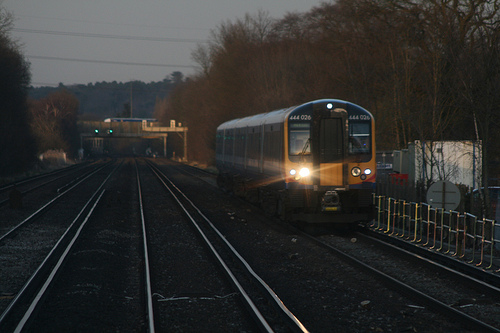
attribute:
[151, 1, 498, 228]
trees — side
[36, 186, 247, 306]
track — part, metal train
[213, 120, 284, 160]
windows — passenger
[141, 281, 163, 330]
train track — part , metal train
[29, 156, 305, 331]
track — part , metal train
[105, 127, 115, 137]
light — stop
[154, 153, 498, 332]
track — right train, train 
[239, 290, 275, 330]
train track — metal train, part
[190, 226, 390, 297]
tracks — several train , running  , parallel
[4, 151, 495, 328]
track — metal train, part 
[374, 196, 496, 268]
fence — metal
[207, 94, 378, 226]
train —  side , blue and yellow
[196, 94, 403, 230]
train — commuter 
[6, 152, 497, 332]
tracks — side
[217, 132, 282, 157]
window —  side 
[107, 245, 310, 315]
traint track — metal train, part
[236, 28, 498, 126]
trees — right side 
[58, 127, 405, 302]
track — right side 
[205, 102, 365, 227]
train — commuter 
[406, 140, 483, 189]
box — green , red warning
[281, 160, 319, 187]
headlight — bright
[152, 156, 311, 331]
track — part, metal train 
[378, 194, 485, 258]
railing — metal 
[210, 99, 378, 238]
train — side 